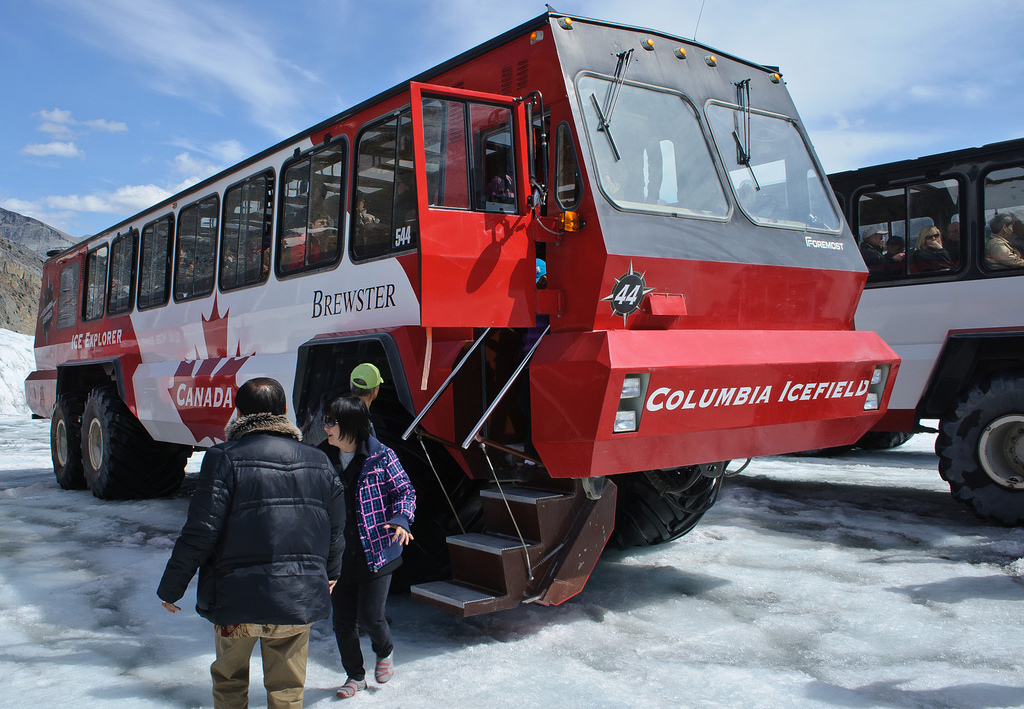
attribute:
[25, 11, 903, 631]
vehicle — large, for driving on snow, canadian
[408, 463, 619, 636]
stairs — extendable, drop down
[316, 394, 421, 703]
girl — walking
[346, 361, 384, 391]
baseball cap — neon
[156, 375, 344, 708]
men — walking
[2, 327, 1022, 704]
ground — icy, snowy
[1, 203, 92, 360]
mountain — in the distance, in distance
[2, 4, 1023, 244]
sky — blue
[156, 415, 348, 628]
coat — black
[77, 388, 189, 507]
tires — large, in the back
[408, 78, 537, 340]
door — red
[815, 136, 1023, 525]
truck — white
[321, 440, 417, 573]
jacket — blue, violet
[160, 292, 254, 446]
maple leaf — red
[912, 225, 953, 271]
woman — blond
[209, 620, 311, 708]
pants — tan